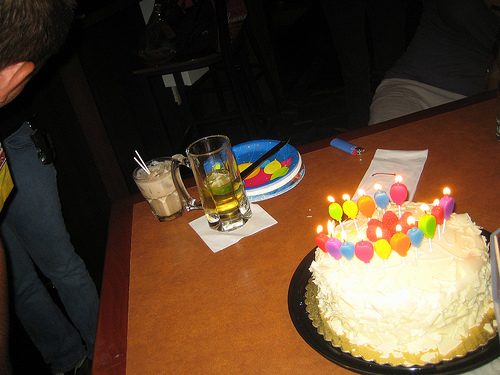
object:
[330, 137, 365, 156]
cigarette lighter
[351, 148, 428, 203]
paper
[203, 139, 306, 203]
paper plates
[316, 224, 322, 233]
flame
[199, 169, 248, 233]
beer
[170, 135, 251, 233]
glass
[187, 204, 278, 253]
napkin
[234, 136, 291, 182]
knife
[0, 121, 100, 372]
jeans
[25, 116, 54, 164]
sunglasses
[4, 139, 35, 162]
pocket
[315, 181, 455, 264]
candles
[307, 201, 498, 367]
cake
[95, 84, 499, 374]
table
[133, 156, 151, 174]
straw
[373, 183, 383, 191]
flame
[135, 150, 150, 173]
straws cup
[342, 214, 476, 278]
andle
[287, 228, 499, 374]
plate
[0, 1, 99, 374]
person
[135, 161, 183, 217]
drink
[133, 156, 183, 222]
cup